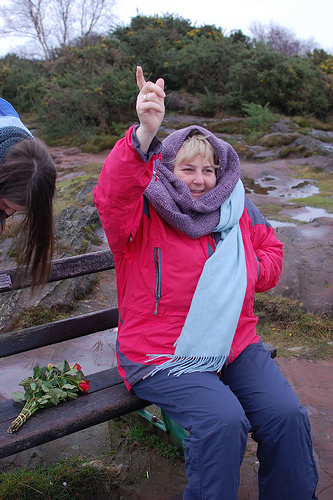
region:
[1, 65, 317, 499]
woman seated on a wooden bench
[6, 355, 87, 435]
bouquet on bench seat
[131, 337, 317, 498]
woman is wearing blue pants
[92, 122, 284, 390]
woman is wearing a hot pink and grey jacket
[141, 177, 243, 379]
pale blue scarf with a fringe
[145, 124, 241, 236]
woman's head is cocooned in purple knit fabric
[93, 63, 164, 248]
woman is holding her right arm up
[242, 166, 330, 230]
puddles of water spread on the ground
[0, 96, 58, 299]
person bending forward over back of bench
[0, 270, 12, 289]
part of a small plaque on bench's back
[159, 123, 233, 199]
head of a person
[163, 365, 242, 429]
thigh of a person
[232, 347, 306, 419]
thigh of a person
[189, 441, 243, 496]
leg of a person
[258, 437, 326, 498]
leg of a person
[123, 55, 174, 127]
hand of a person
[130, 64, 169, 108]
fingers of a person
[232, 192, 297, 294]
arm of a person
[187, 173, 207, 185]
nose of a person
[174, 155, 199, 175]
eye of a person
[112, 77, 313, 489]
a woman on a bench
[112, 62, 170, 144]
the hand of a woman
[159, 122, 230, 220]
the head of a woman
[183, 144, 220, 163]
the hair of a woman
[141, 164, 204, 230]
the purple scarf of a woman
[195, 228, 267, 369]
the blue scarf of a woman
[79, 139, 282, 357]
the red jacket of a woman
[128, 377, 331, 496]
the grey pants of a woman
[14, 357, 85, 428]
a bunch of red flowers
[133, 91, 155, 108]
the ring of a woman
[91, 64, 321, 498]
Woman sitting on park bench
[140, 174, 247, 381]
Blue scarf around neck of woman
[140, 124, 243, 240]
Purple scarf wrapped around woman's head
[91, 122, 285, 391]
Pink coat worn by woman on bench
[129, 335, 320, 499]
Blue pants worn by woman on bench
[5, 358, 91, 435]
Bouquet of flowers on park bench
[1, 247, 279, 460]
Wood bench in the park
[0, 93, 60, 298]
Girl leaning over park bench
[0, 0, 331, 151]
Trees in the back of park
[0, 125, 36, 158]
Blue scarf around girl's neck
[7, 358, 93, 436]
flowers on wood bench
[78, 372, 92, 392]
red rose flower on bench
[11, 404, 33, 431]
rubber bands holding stems of flowers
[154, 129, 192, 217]
purple scarf around lady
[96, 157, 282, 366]
pink lady's jacket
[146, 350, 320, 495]
purple lady's snow pants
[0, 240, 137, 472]
wooden bench in dirt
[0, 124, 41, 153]
blue scarf around girl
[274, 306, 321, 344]
patch of grass in dirt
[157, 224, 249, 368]
light blue scarf on jacket